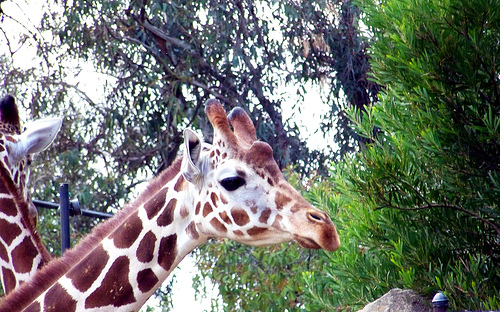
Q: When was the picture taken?
A: Daytime.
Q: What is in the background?
A: Trees.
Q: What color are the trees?
A: Green.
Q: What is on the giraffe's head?
A: Antlers.